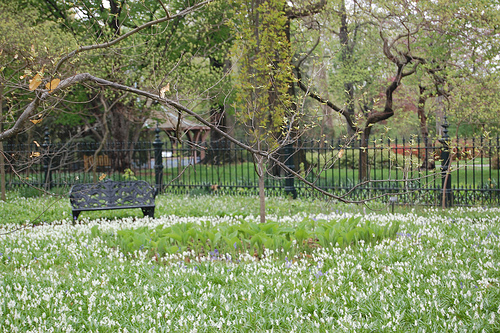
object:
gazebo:
[141, 105, 209, 167]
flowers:
[0, 221, 181, 239]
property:
[3, 136, 500, 332]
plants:
[391, 140, 480, 160]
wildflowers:
[2, 215, 175, 248]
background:
[1, 2, 500, 174]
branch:
[0, 71, 355, 207]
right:
[242, 1, 499, 332]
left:
[1, 1, 262, 332]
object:
[160, 82, 172, 99]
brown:
[362, 112, 376, 181]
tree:
[287, 2, 427, 188]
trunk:
[354, 129, 373, 185]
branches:
[288, 0, 426, 143]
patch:
[118, 215, 400, 252]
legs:
[72, 206, 155, 222]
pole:
[440, 92, 455, 210]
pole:
[41, 129, 56, 189]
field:
[1, 148, 500, 196]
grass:
[7, 166, 499, 207]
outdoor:
[1, 0, 498, 332]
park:
[3, 179, 500, 332]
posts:
[38, 126, 452, 208]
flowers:
[207, 243, 223, 260]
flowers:
[300, 235, 319, 263]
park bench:
[62, 174, 174, 231]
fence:
[2, 131, 485, 220]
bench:
[63, 169, 174, 229]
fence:
[9, 132, 483, 204]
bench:
[62, 174, 164, 227]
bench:
[66, 178, 156, 216]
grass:
[11, 221, 492, 330]